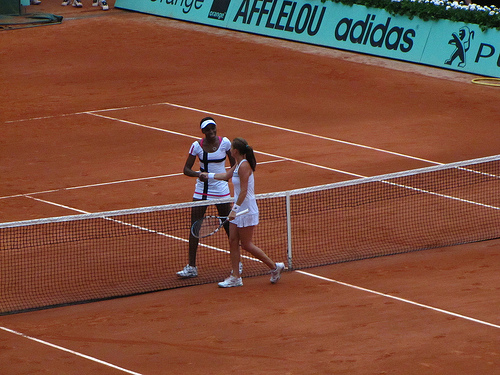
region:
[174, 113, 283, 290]
two tennis players shaking hands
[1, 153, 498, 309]
a long net on a tennis court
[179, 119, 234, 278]
a black tennis player in a white shirt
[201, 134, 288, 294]
a tennis player in a sleeveless shirt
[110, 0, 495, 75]
a row of ads at a tennis court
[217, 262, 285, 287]
a pair of white sneakers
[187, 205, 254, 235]
a blue tennis racket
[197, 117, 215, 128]
a white headband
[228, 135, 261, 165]
a woman with a ponytail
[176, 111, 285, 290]
two athletes shaking hands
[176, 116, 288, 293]
Two tennis players shake over the net.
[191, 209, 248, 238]
Tennis racquet held in the left hand.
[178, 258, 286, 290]
White tennis sneakers worn on a clay court.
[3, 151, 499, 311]
A regulation height tennis net.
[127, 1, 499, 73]
Advertisements for Afflelou, Adidas, and others lining a tennis court.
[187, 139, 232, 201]
Standard women's tennis dress in white.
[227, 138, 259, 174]
White woman with brown ponytail.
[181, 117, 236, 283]
A black tennis player shaking hands with opponent.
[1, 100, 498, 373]
The white lines of a tennis court.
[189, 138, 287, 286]
A female tennis player.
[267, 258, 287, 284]
a woman's tennis shoe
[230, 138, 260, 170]
a woman's long hair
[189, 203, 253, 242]
a large tennis racket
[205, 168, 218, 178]
a white wristband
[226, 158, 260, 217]
a woman's white tank top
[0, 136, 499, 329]
a black and white tennis net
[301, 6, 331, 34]
a black capital letter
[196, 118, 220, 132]
a white visor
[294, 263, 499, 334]
a long white line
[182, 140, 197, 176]
the arm of a woman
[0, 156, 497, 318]
Long tennis net with white on top.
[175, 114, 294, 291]
2 Tennis players shaking hands.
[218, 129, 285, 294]
Lady in white tennis dress.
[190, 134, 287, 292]
Lady holding tennis racket.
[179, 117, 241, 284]
Lady wearing tennis dress with short sleeves.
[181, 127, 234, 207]
Black vertical stripe on tennis dress.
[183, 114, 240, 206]
Pink vertical stripe on tennis dress.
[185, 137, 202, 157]
Pink stripe on short sleeve.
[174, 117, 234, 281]
Lady wearing white sun visor.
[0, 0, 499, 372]
2 Ladies on tennis court shaking hands.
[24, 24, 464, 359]
this is a tennis court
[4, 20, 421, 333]
this is a tennis match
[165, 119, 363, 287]
these are tennis players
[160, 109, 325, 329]
these are pro players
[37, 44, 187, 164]
the clay is burnt orange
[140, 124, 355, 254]
the players are shaking hands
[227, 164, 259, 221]
this player is wearing all white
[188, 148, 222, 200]
the player is wearing red, white, and black